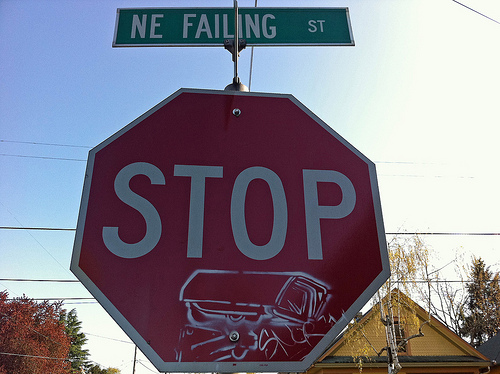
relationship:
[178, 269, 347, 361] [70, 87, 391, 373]
graffiti on stop sign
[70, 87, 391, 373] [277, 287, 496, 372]
stop sign in front of home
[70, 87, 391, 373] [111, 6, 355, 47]
stop sign below street name sign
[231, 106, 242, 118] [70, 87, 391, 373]
screw in stop sign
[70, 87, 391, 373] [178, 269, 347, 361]
stop sign marked with graffiti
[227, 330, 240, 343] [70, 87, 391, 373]
bolt on stop sign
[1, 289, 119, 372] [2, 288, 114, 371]
trees has clear view